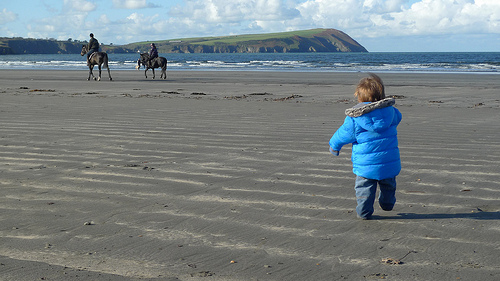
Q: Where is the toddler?
A: Foreground.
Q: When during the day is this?
A: Afternoon.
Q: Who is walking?
A: Toddler.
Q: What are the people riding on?
A: Horses.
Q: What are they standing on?
A: Sand.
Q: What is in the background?
A: Mountains.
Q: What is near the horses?
A: Water.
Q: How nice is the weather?
A: Very nice.